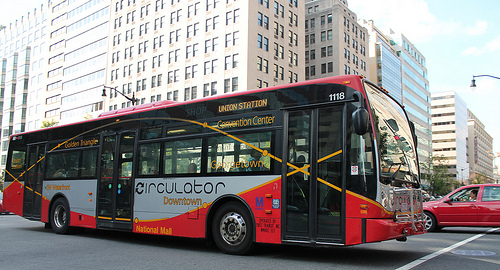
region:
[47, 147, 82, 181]
the window of a bus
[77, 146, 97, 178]
the window of a bus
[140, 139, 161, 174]
the window of a bus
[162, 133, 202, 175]
the window of a bus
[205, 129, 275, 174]
the window of a bus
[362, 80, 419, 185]
the window of a bus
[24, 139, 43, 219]
the door of a bus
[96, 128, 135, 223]
the door of a bus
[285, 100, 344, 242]
the door of a bus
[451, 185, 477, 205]
the window of a car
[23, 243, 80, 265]
Part of the street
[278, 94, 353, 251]
The front door of the bus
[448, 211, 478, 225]
Part of the red car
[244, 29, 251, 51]
Part of the building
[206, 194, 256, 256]
The front tire of the bus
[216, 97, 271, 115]
Letters on the bus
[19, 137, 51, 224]
The back door of the bus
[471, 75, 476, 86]
Part of the streetlight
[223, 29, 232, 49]
A window on the building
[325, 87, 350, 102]
Numbers on the bus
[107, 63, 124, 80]
window of a building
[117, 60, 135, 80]
window of a building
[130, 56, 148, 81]
window of a building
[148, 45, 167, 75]
window of a building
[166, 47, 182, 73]
window of a building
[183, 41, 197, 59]
window of a building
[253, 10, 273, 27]
window of a building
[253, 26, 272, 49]
window of a building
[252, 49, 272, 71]
window of a building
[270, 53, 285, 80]
window of a building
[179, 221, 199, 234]
the bus is red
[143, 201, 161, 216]
the bus is gray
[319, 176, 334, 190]
the line is orange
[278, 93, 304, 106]
the bus is black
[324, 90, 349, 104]
the number is white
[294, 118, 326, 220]
the doors are closed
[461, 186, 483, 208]
the person is driving the car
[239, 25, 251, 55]
the building is white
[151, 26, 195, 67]
the building has lots of windows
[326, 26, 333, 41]
the blind is closed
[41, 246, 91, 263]
Part of the street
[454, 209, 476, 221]
Part of the red car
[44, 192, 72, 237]
The back tire of the bus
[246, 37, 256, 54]
Part of the building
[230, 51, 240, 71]
A window on the building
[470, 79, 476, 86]
Part of the streetlight